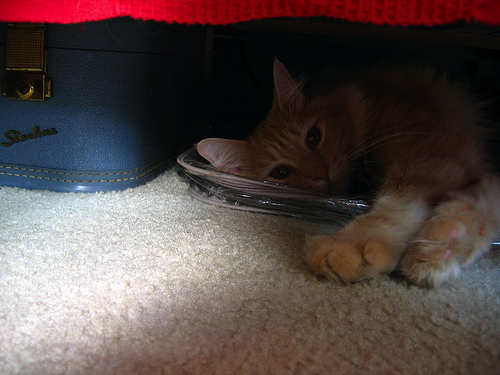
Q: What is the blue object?
A: Suitcase.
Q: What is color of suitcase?
A: Blue.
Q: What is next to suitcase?
A: Cat.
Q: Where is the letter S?
A: On the suitcase.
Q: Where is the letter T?
A: On the suitcase.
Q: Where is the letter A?
A: On the suitcase.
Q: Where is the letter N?
A: On the suitcase.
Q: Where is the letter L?
A: On the suitcase.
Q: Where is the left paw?
A: On the cat.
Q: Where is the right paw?
A: On the cat.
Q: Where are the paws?
A: On the cat.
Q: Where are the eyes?
A: On the cat.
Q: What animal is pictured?
A: Cat.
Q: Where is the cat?
A: On the floor.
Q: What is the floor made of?
A: Carpet.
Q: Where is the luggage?
A: Beside the cat.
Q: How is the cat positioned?
A: Laying down.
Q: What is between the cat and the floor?
A: A plastic bag.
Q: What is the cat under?
A: A piece of furniture.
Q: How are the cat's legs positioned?
A: Outstretched.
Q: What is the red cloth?
A: A blanket.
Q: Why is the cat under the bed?
A: Hiding.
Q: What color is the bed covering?
A: Red.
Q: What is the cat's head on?
A: Plastic.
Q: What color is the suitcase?
A: Blue.